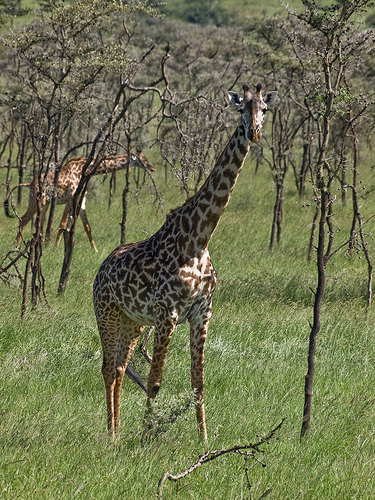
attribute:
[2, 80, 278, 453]
giraffes — facing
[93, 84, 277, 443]
giraffe — standing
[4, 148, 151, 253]
giraffe — obstructed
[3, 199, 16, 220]
hair — black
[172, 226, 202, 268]
spots — brown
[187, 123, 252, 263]
neck — long